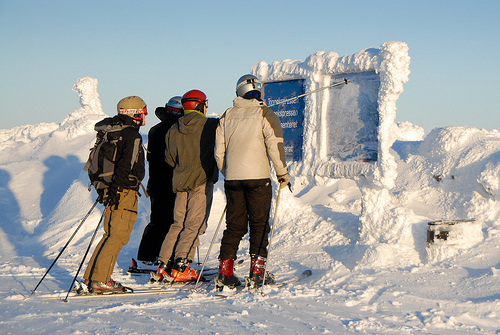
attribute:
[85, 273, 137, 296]
boot — skiing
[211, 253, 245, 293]
boot — skiing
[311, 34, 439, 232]
sculpture made — snow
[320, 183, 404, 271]
boot used — skiing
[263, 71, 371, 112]
pole to point — to point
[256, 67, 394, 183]
blue and white sign — blue and white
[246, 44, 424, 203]
snow-covered sign — snow covered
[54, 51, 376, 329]
people wearing skis — four, wearing skis